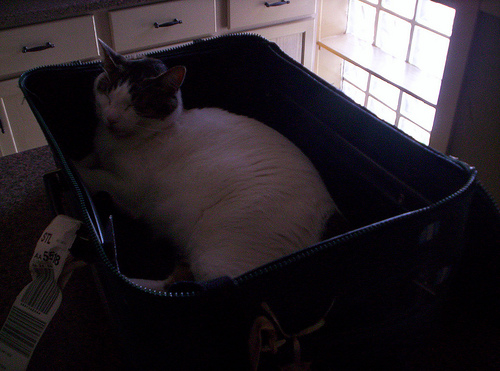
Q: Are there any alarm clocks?
A: No, there are no alarm clocks.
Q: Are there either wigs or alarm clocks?
A: No, there are no alarm clocks or wigs.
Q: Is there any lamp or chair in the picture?
A: No, there are no chairs or lamps.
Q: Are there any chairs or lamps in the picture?
A: No, there are no chairs or lamps.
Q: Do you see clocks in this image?
A: No, there are no clocks.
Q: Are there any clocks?
A: No, there are no clocks.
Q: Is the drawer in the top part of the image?
A: Yes, the drawer is in the top of the image.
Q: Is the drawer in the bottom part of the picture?
A: No, the drawer is in the top of the image.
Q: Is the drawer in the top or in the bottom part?
A: The drawer is in the top of the image.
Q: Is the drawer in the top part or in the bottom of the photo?
A: The drawer is in the top of the image.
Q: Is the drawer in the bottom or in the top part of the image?
A: The drawer is in the top of the image.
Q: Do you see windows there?
A: Yes, there is a window.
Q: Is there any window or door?
A: Yes, there is a window.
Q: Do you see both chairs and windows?
A: No, there is a window but no chairs.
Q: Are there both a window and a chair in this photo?
A: No, there is a window but no chairs.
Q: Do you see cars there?
A: No, there are no cars.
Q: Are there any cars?
A: No, there are no cars.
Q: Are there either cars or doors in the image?
A: No, there are no cars or doors.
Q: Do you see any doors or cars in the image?
A: No, there are no cars or doors.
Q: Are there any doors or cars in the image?
A: No, there are no cars or doors.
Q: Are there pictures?
A: No, there are no pictures.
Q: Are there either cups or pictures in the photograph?
A: No, there are no pictures or cups.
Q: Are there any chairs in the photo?
A: No, there are no chairs.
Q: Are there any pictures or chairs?
A: No, there are no chairs or pictures.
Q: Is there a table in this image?
A: No, there are no tables.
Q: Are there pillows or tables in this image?
A: No, there are no tables or pillows.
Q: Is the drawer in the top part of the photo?
A: Yes, the drawer is in the top of the image.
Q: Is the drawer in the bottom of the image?
A: No, the drawer is in the top of the image.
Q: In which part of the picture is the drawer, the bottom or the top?
A: The drawer is in the top of the image.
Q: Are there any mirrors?
A: No, there are no mirrors.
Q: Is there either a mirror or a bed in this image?
A: No, there are no mirrors or beds.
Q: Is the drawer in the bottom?
A: No, the drawer is in the top of the image.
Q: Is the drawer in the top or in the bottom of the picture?
A: The drawer is in the top of the image.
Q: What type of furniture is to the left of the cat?
A: The piece of furniture is a drawer.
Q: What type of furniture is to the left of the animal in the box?
A: The piece of furniture is a drawer.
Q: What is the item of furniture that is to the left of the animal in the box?
A: The piece of furniture is a drawer.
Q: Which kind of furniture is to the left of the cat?
A: The piece of furniture is a drawer.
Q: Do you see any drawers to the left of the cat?
A: Yes, there is a drawer to the left of the cat.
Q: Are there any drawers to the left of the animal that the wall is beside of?
A: Yes, there is a drawer to the left of the cat.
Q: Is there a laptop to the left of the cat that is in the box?
A: No, there is a drawer to the left of the cat.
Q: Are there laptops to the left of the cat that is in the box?
A: No, there is a drawer to the left of the cat.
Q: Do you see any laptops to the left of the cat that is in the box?
A: No, there is a drawer to the left of the cat.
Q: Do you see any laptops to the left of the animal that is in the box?
A: No, there is a drawer to the left of the cat.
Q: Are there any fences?
A: No, there are no fences.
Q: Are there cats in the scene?
A: Yes, there is a cat.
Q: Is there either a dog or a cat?
A: Yes, there is a cat.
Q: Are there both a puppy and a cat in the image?
A: No, there is a cat but no puppies.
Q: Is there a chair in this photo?
A: No, there are no chairs.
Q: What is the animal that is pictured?
A: The animal is a cat.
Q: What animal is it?
A: The animal is a cat.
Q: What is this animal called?
A: This is a cat.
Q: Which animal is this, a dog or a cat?
A: This is a cat.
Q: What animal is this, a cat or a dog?
A: This is a cat.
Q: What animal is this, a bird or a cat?
A: This is a cat.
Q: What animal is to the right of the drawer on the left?
A: The animal is a cat.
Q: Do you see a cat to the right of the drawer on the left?
A: Yes, there is a cat to the right of the drawer.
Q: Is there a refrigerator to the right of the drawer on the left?
A: No, there is a cat to the right of the drawer.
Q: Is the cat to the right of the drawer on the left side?
A: Yes, the cat is to the right of the drawer.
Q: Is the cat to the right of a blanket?
A: No, the cat is to the right of the drawer.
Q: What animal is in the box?
A: The cat is in the box.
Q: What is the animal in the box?
A: The animal is a cat.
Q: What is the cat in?
A: The cat is in the box.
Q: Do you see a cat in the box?
A: Yes, there is a cat in the box.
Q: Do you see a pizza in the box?
A: No, there is a cat in the box.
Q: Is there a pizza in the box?
A: No, there is a cat in the box.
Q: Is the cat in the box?
A: Yes, the cat is in the box.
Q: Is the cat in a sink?
A: No, the cat is in the box.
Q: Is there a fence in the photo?
A: No, there are no fences.